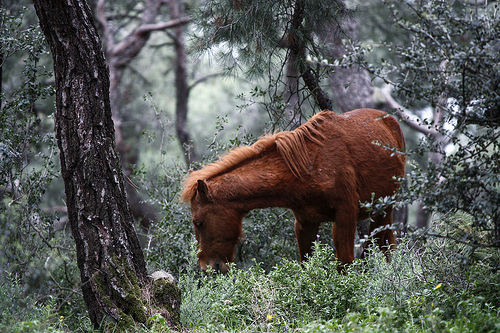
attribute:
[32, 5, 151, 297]
bark — dark brown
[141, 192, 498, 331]
vegetation — overgrown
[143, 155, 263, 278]
head — bent down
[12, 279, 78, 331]
dandelion — tiny, yellow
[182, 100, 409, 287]
horse — reddish brown, reddish and brown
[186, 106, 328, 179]
mane — messy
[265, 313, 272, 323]
flower — small, yellow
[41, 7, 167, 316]
tree — focused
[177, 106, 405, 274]
horse — brown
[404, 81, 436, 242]
tree — white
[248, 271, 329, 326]
flower — yellow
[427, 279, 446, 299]
flower — dandelion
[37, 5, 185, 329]
bark — dark brown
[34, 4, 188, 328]
trunk — tree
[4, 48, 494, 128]
background — desaturated